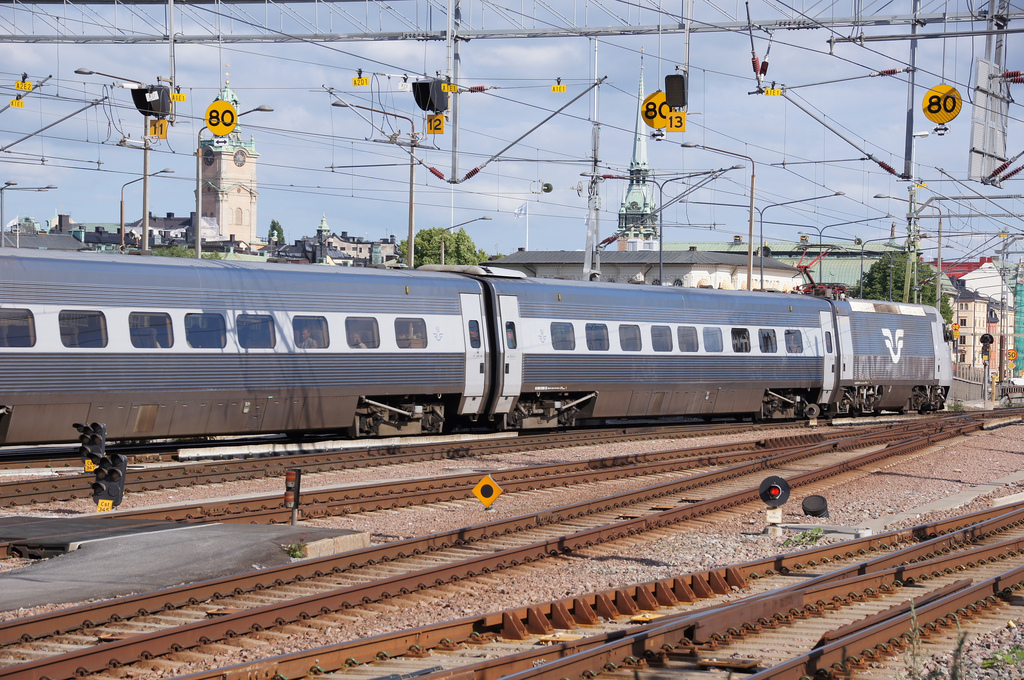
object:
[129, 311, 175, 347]
window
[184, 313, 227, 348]
window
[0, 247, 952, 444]
train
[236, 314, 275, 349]
window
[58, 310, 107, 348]
window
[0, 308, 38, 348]
window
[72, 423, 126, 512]
signal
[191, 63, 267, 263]
building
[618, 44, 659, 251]
building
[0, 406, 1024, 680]
track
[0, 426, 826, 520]
gravel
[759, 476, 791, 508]
light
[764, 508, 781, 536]
post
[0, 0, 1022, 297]
sky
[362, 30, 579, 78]
cloud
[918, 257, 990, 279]
roof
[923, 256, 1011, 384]
building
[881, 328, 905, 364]
logo